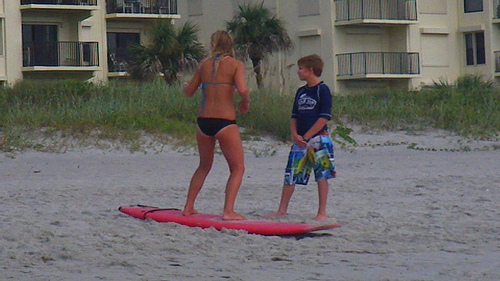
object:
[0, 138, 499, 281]
sand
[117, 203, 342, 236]
surfboard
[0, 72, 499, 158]
grass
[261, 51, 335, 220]
boy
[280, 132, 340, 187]
shorts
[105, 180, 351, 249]
surfboard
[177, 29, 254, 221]
girl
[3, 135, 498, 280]
beach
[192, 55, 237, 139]
bikini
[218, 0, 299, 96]
tree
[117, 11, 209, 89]
tree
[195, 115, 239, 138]
bathing suit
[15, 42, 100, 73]
balcony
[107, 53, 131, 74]
chair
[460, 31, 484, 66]
window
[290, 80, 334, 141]
shirt